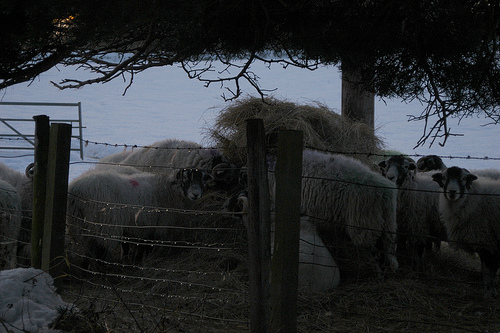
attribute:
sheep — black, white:
[424, 164, 499, 301]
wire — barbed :
[311, 140, 498, 166]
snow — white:
[1, 57, 498, 182]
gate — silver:
[2, 98, 86, 164]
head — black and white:
[369, 145, 413, 190]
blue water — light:
[141, 75, 206, 138]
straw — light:
[206, 96, 384, 152]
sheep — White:
[243, 150, 405, 278]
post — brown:
[328, 47, 385, 177]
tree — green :
[447, 57, 469, 90]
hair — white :
[314, 167, 364, 205]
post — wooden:
[244, 116, 276, 321]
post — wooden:
[270, 127, 302, 323]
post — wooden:
[44, 122, 73, 284]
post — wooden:
[28, 112, 50, 269]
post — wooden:
[41, 115, 75, 278]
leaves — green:
[54, 1, 499, 119]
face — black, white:
[181, 167, 207, 201]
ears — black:
[437, 173, 471, 178]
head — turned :
[430, 166, 478, 201]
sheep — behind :
[0, 140, 499, 292]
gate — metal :
[0, 99, 92, 171]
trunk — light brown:
[340, 57, 375, 127]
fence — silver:
[62, 197, 247, 329]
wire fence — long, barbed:
[77, 199, 216, 311]